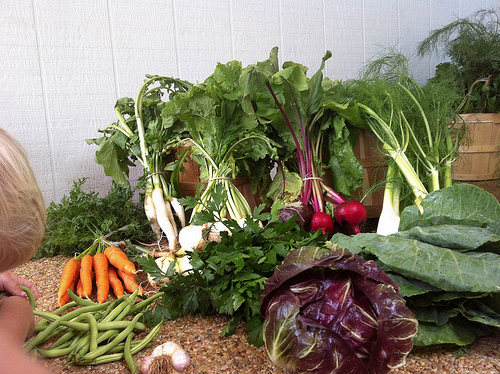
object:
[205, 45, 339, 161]
tops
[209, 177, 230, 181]
band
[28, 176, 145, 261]
leaves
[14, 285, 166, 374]
beans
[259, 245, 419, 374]
lettuce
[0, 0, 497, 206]
wall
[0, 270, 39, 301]
hand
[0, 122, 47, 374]
child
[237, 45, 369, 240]
beets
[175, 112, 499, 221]
barrel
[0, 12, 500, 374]
greens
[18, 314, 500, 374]
ground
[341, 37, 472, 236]
vegetable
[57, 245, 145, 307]
carrot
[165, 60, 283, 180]
tops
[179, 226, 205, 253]
onions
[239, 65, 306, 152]
leaves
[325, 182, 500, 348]
leaves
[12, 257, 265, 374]
table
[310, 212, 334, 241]
radish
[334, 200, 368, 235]
radish